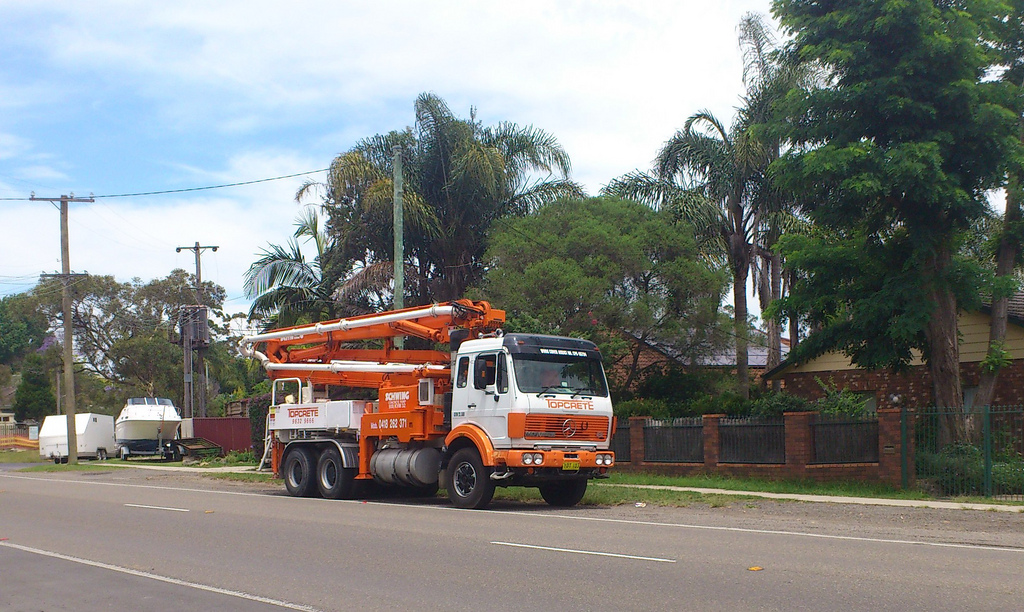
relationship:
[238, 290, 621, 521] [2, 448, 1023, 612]
truck on street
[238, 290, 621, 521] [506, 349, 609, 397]
truck has windshield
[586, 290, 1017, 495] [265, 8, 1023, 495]
houses behind trees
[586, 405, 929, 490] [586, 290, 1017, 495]
fence around houses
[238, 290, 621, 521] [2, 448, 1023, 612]
truck on road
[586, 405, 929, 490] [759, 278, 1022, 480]
fence surrounds houses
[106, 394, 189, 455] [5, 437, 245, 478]
boat on lawn